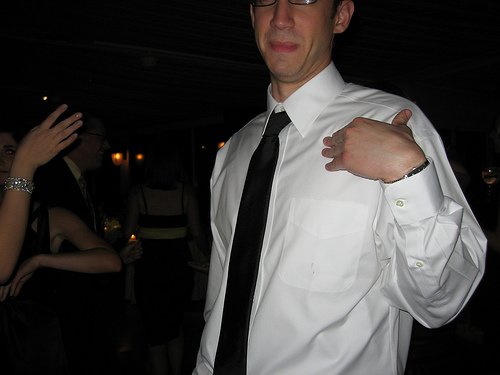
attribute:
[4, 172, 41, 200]
bracelet — silver 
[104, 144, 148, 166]
lights — orange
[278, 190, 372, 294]
pocket — white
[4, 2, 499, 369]
background — dark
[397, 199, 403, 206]
button — white 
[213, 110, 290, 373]
tie — black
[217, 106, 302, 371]
tie — black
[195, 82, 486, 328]
shirt — white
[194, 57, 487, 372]
shirt — white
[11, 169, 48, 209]
bracelet — silver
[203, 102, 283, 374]
necktie — black